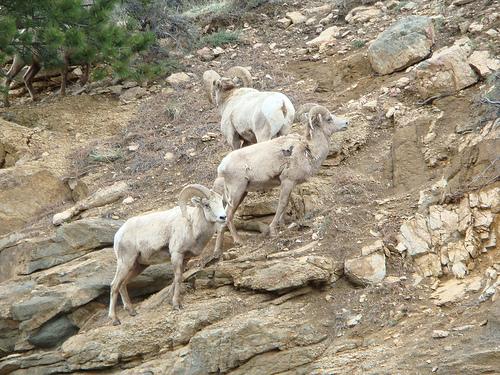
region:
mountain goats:
[103, 67, 353, 340]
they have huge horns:
[170, 147, 243, 250]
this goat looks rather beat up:
[274, 139, 319, 176]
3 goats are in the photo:
[76, 52, 361, 343]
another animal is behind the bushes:
[0, 22, 99, 99]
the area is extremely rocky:
[276, 17, 498, 316]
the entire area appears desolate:
[87, 47, 499, 299]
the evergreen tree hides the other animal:
[19, 11, 181, 101]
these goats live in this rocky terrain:
[43, 57, 392, 340]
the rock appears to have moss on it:
[381, 15, 433, 80]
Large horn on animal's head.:
[177, 180, 225, 229]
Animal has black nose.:
[217, 211, 230, 228]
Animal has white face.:
[207, 197, 262, 239]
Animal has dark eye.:
[197, 197, 222, 224]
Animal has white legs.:
[88, 283, 240, 306]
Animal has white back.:
[124, 215, 175, 235]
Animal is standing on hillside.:
[77, 261, 219, 309]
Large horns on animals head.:
[302, 100, 328, 137]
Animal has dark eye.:
[323, 112, 335, 130]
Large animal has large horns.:
[194, 67, 285, 103]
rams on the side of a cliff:
[100, 61, 367, 331]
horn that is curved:
[169, 180, 210, 213]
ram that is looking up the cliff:
[205, 100, 352, 252]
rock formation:
[362, 194, 497, 300]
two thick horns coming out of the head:
[195, 58, 259, 110]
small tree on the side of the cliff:
[5, 4, 172, 104]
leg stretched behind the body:
[212, 182, 247, 259]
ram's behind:
[258, 96, 298, 138]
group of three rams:
[91, 64, 385, 327]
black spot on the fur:
[281, 140, 296, 162]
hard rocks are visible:
[335, 141, 482, 326]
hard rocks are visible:
[335, 214, 426, 312]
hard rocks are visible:
[365, 217, 452, 358]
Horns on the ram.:
[179, 177, 249, 227]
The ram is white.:
[118, 222, 195, 255]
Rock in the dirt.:
[400, 201, 474, 237]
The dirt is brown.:
[328, 211, 387, 245]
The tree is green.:
[7, 8, 89, 58]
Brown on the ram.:
[257, 140, 304, 163]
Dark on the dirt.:
[474, 83, 499, 117]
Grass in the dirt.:
[209, 31, 238, 51]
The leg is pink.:
[152, 270, 187, 304]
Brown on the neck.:
[218, 67, 253, 99]